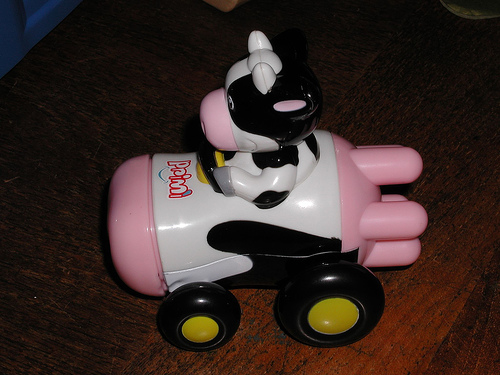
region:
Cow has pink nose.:
[201, 104, 231, 123]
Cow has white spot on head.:
[228, 58, 244, 85]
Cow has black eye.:
[217, 97, 236, 112]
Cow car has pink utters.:
[345, 132, 400, 239]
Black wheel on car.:
[273, 282, 395, 367]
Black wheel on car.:
[141, 254, 232, 359]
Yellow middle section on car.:
[317, 300, 349, 357]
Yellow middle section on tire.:
[183, 309, 220, 369]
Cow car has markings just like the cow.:
[164, 171, 336, 275]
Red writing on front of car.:
[162, 152, 212, 244]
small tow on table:
[87, 31, 412, 352]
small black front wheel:
[158, 294, 243, 345]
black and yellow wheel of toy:
[134, 271, 229, 369]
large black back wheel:
[295, 247, 405, 321]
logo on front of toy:
[160, 157, 197, 222]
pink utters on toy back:
[351, 92, 446, 312]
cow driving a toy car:
[14, 48, 401, 256]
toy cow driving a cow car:
[0, 30, 377, 292]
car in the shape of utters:
[52, 124, 479, 332]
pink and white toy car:
[55, 72, 415, 243]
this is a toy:
[95, 12, 430, 355]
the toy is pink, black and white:
[100, 27, 432, 349]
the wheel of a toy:
[267, 265, 382, 350]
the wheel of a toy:
[143, 288, 238, 353]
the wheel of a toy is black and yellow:
[273, 263, 384, 344]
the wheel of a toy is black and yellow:
[150, 280, 240, 355]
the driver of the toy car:
[195, 27, 326, 203]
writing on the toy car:
[160, 146, 202, 204]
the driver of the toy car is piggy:
[191, 28, 338, 206]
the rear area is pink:
[336, 121, 435, 266]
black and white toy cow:
[183, 28, 320, 206]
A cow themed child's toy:
[104, 36, 439, 353]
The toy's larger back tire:
[285, 257, 385, 350]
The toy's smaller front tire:
[164, 280, 234, 360]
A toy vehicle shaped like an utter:
[116, 127, 432, 291]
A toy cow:
[183, 29, 323, 199]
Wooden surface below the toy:
[386, 11, 498, 364]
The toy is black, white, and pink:
[105, 139, 405, 279]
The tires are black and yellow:
[281, 265, 392, 347]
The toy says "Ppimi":
[158, 155, 194, 207]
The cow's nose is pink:
[195, 90, 240, 152]